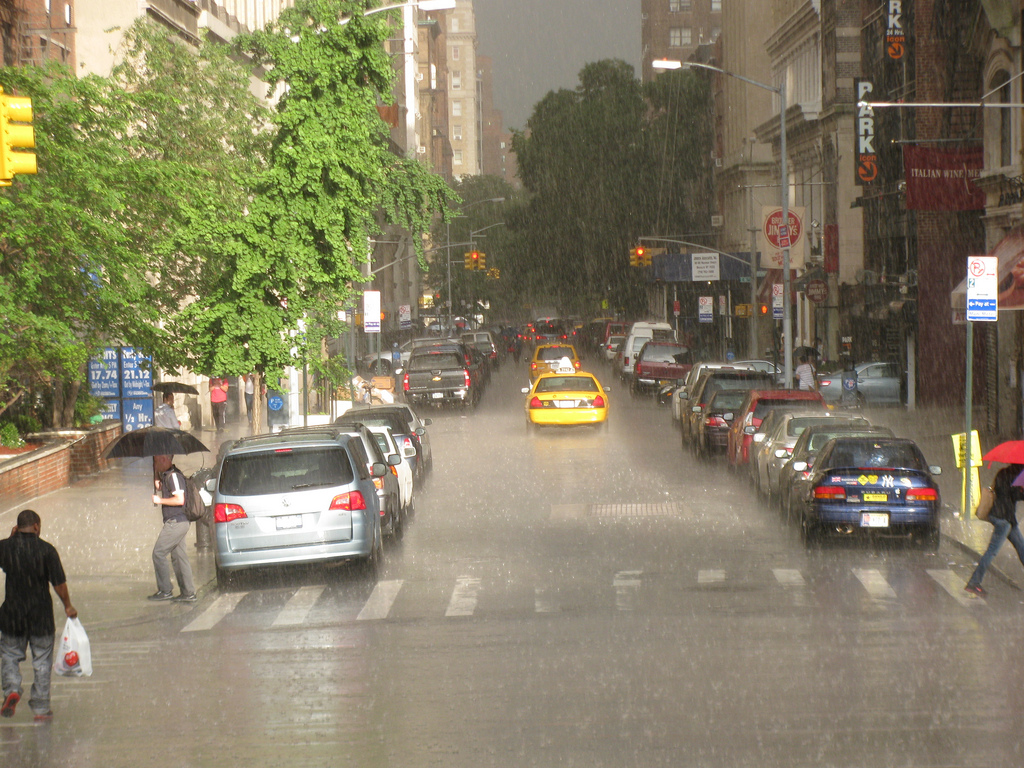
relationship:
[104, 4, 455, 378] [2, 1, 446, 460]
leaves on tree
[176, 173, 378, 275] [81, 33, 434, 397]
leaves on tree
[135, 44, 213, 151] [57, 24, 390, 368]
leaves on tree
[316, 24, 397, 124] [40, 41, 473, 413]
leaves on tree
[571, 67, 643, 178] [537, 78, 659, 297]
leaves on tree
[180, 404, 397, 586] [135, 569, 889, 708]
car on street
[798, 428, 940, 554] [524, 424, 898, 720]
car on street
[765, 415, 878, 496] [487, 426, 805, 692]
car on street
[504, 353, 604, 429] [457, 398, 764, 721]
car on street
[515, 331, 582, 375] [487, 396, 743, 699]
car on street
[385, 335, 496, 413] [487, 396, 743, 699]
car on street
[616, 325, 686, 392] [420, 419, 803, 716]
car on street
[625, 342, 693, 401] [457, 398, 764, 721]
car on street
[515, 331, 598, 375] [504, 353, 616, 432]
taxi in front of car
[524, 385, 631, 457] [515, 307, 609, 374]
taxi behind taxi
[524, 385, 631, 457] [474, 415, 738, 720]
taxi on road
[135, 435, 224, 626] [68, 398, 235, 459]
person holding umbrella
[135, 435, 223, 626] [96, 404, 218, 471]
person holding umbrella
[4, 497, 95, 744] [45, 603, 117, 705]
person holding bag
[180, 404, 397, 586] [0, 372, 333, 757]
car parked next to sidewalk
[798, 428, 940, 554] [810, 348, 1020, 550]
car parked next to sidewalk